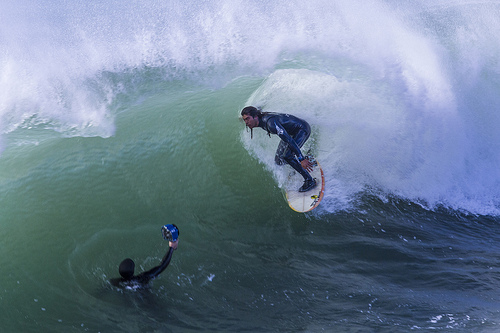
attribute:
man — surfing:
[241, 105, 321, 194]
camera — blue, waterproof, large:
[159, 223, 185, 241]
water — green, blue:
[1, 71, 499, 332]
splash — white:
[0, 2, 499, 217]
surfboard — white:
[283, 169, 328, 214]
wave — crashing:
[2, 1, 499, 220]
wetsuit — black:
[259, 111, 313, 180]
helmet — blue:
[159, 222, 187, 245]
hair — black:
[118, 256, 144, 279]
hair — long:
[240, 105, 265, 120]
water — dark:
[1, 190, 498, 331]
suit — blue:
[260, 110, 313, 178]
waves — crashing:
[0, 0, 500, 221]